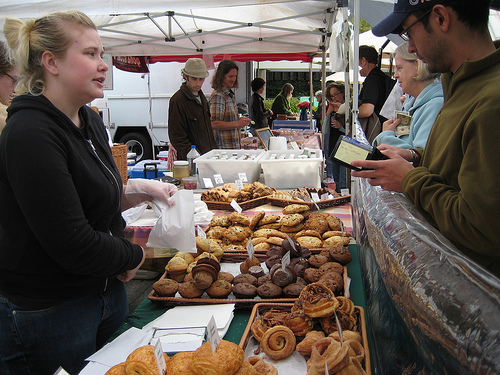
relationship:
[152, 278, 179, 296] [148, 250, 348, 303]
muffin on top of tray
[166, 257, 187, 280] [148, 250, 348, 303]
muffin on top of tray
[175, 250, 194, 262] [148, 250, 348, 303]
muffin on top of tray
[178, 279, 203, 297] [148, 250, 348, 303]
muffin on top of tray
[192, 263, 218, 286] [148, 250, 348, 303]
muffin on top of tray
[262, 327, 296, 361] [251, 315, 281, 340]
donut next to donut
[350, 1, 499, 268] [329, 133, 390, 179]
man has wallet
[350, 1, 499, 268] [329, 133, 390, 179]
man opening wallet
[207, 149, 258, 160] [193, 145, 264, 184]
goods inside container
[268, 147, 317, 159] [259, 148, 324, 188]
goods inside container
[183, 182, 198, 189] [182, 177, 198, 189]
goods inside container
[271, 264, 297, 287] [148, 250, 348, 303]
muffin on top of tray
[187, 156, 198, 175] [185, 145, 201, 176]
drink inside bottle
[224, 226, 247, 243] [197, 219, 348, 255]
cookie on top of tray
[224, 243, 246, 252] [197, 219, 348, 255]
cookie on top of tray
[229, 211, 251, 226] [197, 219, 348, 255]
cookie on top of tray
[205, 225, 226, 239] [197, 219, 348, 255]
cookie on top of tray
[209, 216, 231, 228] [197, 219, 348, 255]
cookie on top of tray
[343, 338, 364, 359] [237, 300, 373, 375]
donut on top of tray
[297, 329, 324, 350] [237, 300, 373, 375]
donut on top of tray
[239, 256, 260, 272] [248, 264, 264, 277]
muffin next to muffin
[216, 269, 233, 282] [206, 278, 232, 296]
muffin next to muffin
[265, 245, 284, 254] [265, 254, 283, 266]
muffin next to muffin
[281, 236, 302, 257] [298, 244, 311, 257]
muffin next to muffin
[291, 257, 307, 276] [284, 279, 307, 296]
muffin next to muffin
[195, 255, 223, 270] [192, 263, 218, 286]
muffin next to muffin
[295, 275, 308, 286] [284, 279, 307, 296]
muffin next to muffin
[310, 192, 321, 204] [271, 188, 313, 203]
sign posted for pastries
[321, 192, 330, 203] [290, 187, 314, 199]
sign posted for pastries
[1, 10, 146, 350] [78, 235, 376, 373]
chef standing at counter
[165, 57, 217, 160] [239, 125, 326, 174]
chef standing at counter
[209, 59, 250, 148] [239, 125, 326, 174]
chef standing at counter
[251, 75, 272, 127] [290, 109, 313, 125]
chef standing at counter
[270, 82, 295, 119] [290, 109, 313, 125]
chef standing at counter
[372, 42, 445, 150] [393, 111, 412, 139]
lady holding money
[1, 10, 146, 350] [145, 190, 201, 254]
chef selling food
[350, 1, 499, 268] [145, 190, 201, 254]
man buying food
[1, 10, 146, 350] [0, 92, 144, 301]
chef wearing jacket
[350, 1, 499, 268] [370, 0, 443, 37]
man wearing hat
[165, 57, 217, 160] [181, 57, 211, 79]
chef wearing hat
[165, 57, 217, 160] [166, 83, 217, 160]
chef wearing jacket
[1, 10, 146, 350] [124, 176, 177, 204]
chef wearing glove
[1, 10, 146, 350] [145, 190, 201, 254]
chef serving food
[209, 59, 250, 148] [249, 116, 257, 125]
chef serving food